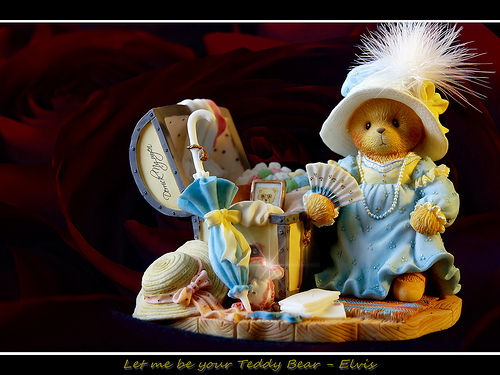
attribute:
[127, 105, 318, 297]
trunk — open, figural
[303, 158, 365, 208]
fan — open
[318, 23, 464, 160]
hat — figural straw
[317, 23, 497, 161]
hat — large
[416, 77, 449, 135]
yellow bow — blue, figural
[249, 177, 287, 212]
framed photo — figural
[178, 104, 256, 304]
umbrella — blue